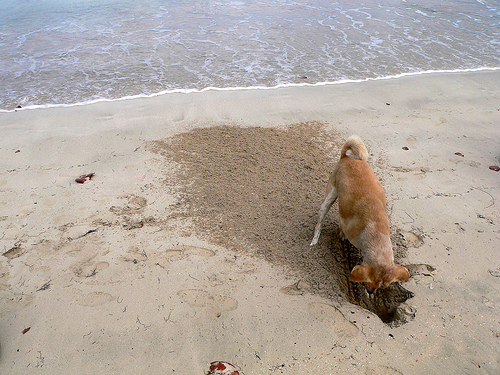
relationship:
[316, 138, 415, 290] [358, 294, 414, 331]
dog digging a hole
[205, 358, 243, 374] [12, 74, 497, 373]
red object in sand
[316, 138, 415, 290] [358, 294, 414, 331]
dog looking in hole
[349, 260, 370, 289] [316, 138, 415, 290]
ear of dog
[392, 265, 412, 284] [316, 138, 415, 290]
ear of dog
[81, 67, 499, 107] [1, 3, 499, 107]
edge of water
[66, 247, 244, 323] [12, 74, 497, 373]
prints in sand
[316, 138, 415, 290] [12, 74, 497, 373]
dog on sand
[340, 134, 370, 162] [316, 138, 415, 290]
tail of dog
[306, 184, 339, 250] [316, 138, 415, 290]
leg of dog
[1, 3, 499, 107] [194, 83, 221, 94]
water has foam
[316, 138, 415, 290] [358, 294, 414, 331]
dog digging hole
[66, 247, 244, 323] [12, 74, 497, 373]
prints on sand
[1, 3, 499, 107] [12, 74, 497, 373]
water coming up on sand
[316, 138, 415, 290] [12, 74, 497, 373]
dog digging in sand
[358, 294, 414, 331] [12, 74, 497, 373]
hole in sand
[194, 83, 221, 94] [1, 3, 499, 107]
foam on water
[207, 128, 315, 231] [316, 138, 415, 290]
sand behind dog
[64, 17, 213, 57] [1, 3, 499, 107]
wripples on water